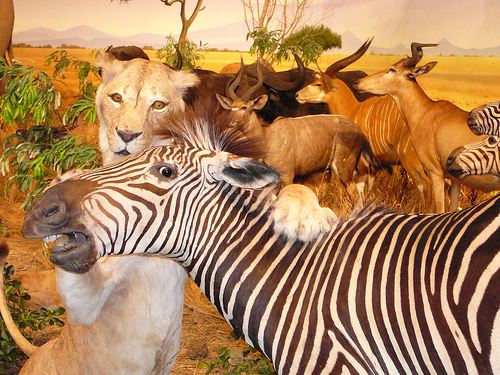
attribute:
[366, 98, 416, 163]
stripes — white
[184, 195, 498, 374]
stripes — white, black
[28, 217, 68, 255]
mouth — opened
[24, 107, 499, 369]
zebra — white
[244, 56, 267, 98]
antler — long, curved, grey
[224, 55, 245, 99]
antler — grey, long, curved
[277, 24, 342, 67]
tree — small, green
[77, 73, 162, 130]
eyes — brown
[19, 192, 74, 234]
nose — black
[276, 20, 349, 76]
tree — green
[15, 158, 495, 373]
zebra — white, black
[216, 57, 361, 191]
antelope — brown, grey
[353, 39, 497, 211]
antelope — brown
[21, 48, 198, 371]
cat — black and white